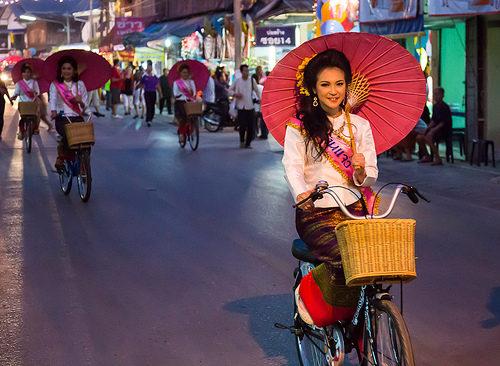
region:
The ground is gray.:
[100, 260, 240, 365]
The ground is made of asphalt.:
[86, 271, 225, 362]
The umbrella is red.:
[228, 23, 442, 161]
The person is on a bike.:
[31, 40, 116, 204]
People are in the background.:
[81, 45, 281, 162]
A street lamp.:
[13, 7, 80, 57]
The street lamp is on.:
[13, 8, 73, 60]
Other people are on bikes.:
[6, 48, 216, 212]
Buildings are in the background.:
[2, 2, 494, 170]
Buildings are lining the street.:
[0, 0, 499, 175]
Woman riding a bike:
[239, 28, 426, 358]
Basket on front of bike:
[335, 205, 431, 298]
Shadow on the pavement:
[226, 265, 286, 356]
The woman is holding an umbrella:
[237, 42, 449, 155]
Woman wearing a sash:
[273, 110, 398, 216]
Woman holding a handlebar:
[295, 172, 325, 234]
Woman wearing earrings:
[296, 98, 330, 113]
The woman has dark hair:
[293, 42, 351, 135]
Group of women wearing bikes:
[17, 47, 231, 197]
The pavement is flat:
[42, 205, 199, 361]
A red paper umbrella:
[37, 46, 117, 94]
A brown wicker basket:
[335, 212, 421, 289]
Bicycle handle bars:
[291, 172, 431, 220]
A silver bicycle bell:
[313, 177, 332, 194]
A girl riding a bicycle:
[256, 29, 440, 364]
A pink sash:
[286, 108, 393, 221]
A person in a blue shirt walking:
[128, 58, 168, 126]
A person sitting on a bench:
[421, 83, 471, 178]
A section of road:
[115, 138, 265, 365]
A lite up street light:
[9, 7, 89, 47]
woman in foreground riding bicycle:
[248, 11, 448, 365]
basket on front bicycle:
[326, 214, 425, 289]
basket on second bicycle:
[63, 114, 98, 151]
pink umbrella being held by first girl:
[249, 22, 439, 191]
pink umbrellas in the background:
[3, 43, 215, 105]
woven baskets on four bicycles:
[14, 82, 415, 289]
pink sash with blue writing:
[299, 113, 385, 205]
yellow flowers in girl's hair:
[295, 52, 320, 98]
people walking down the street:
[97, 51, 276, 131]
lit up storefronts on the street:
[94, 5, 479, 130]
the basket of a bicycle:
[331, 211, 419, 282]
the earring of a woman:
[310, 95, 317, 105]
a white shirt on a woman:
[276, 110, 376, 211]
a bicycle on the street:
[271, 181, 423, 358]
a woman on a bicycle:
[275, 45, 377, 332]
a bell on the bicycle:
[313, 177, 328, 193]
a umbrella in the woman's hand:
[255, 26, 432, 168]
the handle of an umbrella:
[338, 105, 361, 174]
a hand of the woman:
[351, 150, 366, 174]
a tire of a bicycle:
[373, 294, 417, 364]